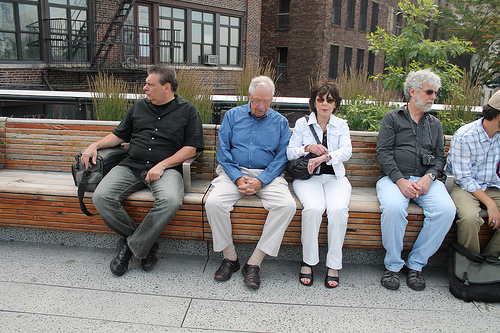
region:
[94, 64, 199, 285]
a man on a bench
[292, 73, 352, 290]
a woman on a bench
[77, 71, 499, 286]
people sitting on a bench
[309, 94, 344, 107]
glasses on a womans head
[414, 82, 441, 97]
glasses on a mans head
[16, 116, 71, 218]
a wooden park brench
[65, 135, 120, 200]
a gray suit case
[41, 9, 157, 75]
a starway on a building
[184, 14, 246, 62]
windows on a building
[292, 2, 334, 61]
a brick wall on a building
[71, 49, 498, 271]
five people sitting on a bench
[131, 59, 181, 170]
a man wearing a black shirt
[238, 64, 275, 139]
a man looking down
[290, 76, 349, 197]
a woman holding a purse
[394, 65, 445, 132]
a man wearing glasses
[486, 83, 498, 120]
a man wearing a cap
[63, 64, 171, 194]
a man with his arm on a bag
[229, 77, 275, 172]
a man wearing a blue shirt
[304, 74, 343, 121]
a woman with brown hair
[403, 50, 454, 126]
a man with grey hair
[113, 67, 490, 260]
people sitting on the bench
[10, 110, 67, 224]
the bench is brown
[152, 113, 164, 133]
buttons on the shirt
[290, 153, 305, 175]
the women has a black purse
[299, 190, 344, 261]
the pants are white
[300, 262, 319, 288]
women is wearing sandals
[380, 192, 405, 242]
light blue jeans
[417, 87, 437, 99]
man is wearing sunglasses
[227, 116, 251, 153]
a blue long sleeve shirt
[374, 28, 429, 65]
the leaves on the trees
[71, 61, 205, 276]
Man in black shirt sitting on bench with bag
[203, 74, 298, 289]
Older white-haired man sitting on bench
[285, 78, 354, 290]
Brown-haired woman sitting on bench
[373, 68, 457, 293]
Gray-haired man wearing sunglasses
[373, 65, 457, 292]
Gray-haired man sitting on bench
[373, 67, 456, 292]
Gray-haired man wearing camera on strap around neck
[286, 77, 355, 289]
Woman dressed in white and wearing sunglasses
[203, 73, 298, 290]
Older man wearing blue shirt and khaki pants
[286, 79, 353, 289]
Woman wearing sandals and holding purse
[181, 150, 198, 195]
Metal arm rest of bench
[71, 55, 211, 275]
A man in a black shirt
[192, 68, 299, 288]
A man in a blue shirt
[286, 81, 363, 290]
A woman in a white blouse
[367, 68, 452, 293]
A man in a gray shirt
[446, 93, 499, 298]
A man in a plaid shirt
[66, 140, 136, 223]
A duffel bag on the bench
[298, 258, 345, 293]
A black pair of sandals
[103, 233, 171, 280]
A pair of shiny black shoes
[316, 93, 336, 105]
Sunglasses on the woman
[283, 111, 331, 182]
The woman's black purse